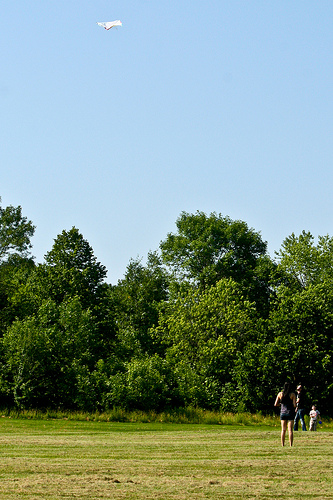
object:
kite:
[96, 19, 123, 31]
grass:
[0, 407, 333, 500]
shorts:
[280, 413, 296, 420]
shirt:
[280, 392, 295, 415]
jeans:
[294, 408, 306, 431]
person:
[274, 382, 298, 448]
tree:
[0, 307, 55, 410]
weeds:
[107, 405, 131, 422]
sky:
[0, 0, 333, 307]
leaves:
[225, 339, 229, 343]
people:
[308, 404, 321, 432]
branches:
[169, 262, 203, 273]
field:
[0, 408, 332, 500]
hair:
[282, 381, 293, 400]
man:
[294, 385, 307, 432]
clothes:
[279, 392, 295, 421]